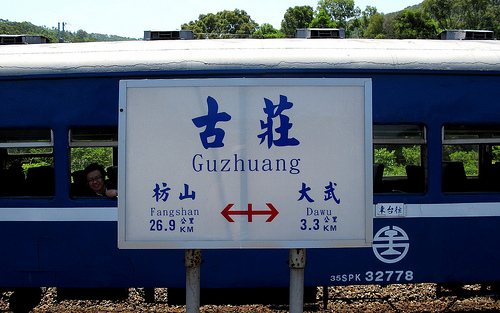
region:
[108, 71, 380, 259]
Sign has chinese letters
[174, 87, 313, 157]
Big blue Chinese letters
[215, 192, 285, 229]
Red arrow points right and left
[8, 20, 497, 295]
Passenger train is blue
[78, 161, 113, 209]
Person inside a train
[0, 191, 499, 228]
Train has a white stripe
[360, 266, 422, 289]
Number in the train is 32778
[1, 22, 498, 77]
Roof of train is white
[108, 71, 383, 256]
Sign is white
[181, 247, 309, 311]
Two poles holding teh sign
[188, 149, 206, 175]
a letter is written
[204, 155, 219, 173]
a letter is written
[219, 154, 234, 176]
a letter is written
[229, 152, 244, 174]
a letter is written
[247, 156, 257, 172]
a letter is written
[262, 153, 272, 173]
a letter is written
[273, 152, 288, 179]
a letter is written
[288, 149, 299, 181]
a letter is written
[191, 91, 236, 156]
a letter is written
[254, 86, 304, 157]
a letter is written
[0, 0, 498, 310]
an outside scene of a train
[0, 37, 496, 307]
a blue and white train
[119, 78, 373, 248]
the Guzhuang sign to Fangshan and Dawu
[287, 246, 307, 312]
the sign is attached to two metal poles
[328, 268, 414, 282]
the identification number of the train is displayed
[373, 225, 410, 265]
the train line logo is displayed on the train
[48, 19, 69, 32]
an industrial business in the distance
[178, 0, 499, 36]
trees and shrubs behind the train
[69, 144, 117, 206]
a passenger ridding the train line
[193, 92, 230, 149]
Blue Chinese symbol above the letters Guz.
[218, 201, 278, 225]
Red arrows facing right and left.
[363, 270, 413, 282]
The numbers 32778.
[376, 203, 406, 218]
Chinese symbols above a round logo on the right side of a train.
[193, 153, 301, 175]
The word Guzhuang on a sign.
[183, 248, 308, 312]
Two metal poles on the bottom of a Chinese sign.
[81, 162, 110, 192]
Persons smiling face to the left of a sign.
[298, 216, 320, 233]
The numbers 3.3.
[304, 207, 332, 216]
The word Dawu.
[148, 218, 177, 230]
The number 26.9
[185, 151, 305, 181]
blue writing on the sign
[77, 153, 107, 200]
the head of a woman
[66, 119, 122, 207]
a window on the train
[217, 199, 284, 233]
a red arrow on the sign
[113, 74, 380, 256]
a white sign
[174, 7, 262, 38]
a green leafy tree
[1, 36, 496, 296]
a blue train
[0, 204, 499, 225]
a white stripe on the train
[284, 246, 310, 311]
a gray sign post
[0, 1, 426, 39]
a gray sky